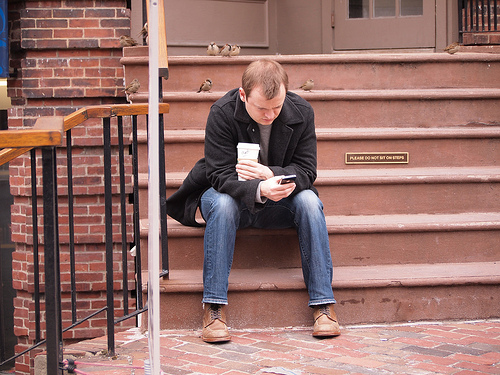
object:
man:
[166, 59, 342, 344]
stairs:
[122, 51, 498, 329]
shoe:
[201, 301, 234, 342]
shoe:
[312, 303, 343, 336]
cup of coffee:
[234, 141, 260, 182]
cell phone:
[278, 174, 297, 190]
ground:
[33, 318, 500, 374]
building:
[0, 0, 500, 374]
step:
[122, 49, 498, 99]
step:
[134, 94, 497, 141]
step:
[133, 131, 499, 188]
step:
[135, 175, 500, 234]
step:
[138, 210, 500, 269]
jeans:
[198, 186, 339, 308]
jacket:
[167, 90, 318, 227]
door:
[325, 0, 445, 54]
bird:
[205, 40, 220, 57]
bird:
[126, 77, 142, 95]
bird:
[197, 79, 215, 95]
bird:
[295, 79, 319, 93]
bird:
[221, 41, 237, 57]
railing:
[1, 98, 171, 374]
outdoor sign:
[344, 150, 414, 165]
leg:
[198, 187, 241, 306]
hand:
[235, 160, 274, 184]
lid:
[235, 143, 262, 151]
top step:
[125, 47, 499, 66]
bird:
[229, 44, 241, 56]